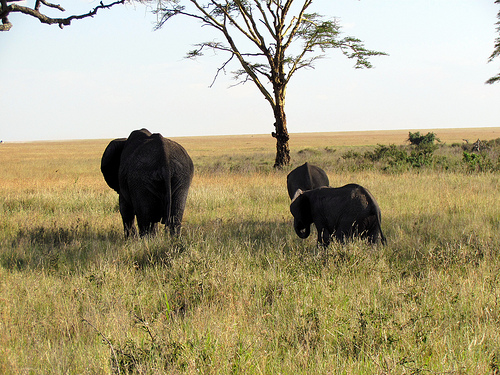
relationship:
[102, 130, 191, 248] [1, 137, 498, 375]
elephant in grass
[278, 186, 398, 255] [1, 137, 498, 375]
elephant in grass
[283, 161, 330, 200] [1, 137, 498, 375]
elephant in grass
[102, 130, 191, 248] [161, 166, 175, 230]
elephant has tail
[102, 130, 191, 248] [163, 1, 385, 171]
elephant near tree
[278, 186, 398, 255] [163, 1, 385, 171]
elephant near tree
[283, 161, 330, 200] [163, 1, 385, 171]
elephant near tree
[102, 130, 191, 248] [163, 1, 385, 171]
elephant faces tree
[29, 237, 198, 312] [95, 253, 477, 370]
shadow in grass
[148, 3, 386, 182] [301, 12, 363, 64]
tree with leaves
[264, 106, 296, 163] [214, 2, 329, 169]
trunk of tree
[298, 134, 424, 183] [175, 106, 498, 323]
brown grass in savanah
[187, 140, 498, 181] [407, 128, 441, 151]
patch of vegetation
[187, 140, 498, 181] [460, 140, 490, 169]
patch of vegetation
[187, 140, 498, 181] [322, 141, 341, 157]
patch of vegetation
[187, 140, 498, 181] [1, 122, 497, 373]
patch on ground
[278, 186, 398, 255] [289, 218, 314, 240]
elephant with trunk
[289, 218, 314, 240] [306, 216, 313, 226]
trunk near mouth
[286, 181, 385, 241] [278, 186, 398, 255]
profile of elephant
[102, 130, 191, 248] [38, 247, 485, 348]
elephant standing in grass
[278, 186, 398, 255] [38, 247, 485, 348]
elephant standing in grass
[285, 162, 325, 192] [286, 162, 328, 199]
backside of elephant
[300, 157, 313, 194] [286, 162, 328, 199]
tail of elephant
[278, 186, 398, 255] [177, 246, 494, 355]
elephant standing in grass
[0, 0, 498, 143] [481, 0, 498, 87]
sky behind leafy twigs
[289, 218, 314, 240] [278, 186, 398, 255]
trunk on elephant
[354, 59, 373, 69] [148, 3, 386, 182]
leaves on tree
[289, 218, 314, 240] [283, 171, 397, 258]
trunk in elephant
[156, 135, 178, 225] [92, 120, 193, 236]
tail on elephants